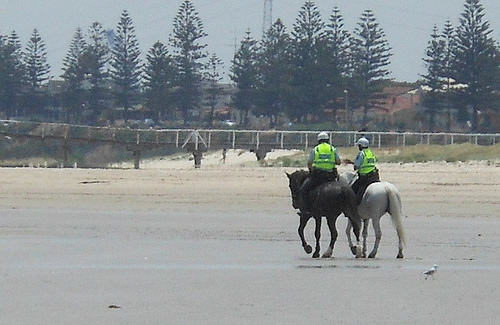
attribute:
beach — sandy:
[4, 156, 499, 325]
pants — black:
[300, 171, 341, 217]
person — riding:
[352, 137, 381, 200]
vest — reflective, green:
[313, 144, 338, 171]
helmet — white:
[358, 135, 369, 148]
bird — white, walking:
[421, 264, 440, 282]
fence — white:
[0, 119, 500, 152]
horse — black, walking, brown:
[284, 168, 361, 258]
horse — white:
[342, 171, 407, 260]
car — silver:
[222, 118, 238, 126]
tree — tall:
[165, 1, 210, 129]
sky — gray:
[0, 0, 500, 86]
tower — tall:
[263, 0, 274, 46]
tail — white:
[387, 184, 406, 249]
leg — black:
[324, 214, 338, 261]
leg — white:
[367, 215, 382, 259]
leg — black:
[299, 213, 313, 255]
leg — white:
[346, 220, 356, 256]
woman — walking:
[218, 148, 229, 166]